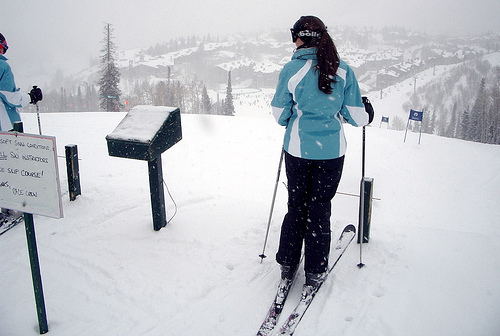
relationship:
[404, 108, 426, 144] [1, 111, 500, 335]
ski marker in snow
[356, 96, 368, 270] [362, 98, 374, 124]
ski pole in hand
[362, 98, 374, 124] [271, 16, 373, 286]
hand of girl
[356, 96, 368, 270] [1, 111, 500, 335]
ski pole in snow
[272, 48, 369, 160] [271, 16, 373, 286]
jacket on girl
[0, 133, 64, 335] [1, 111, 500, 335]
sign in snow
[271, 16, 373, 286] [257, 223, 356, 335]
girl in skis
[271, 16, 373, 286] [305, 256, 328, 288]
girl in ski boot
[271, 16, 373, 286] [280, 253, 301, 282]
girl in ski boot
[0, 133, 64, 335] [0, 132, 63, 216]
sign with warning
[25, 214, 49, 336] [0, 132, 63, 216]
pole holding warning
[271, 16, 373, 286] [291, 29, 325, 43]
girl in goggles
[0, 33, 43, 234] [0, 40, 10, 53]
person in goggles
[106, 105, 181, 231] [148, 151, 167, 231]
box on post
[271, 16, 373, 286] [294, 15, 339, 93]
girl with hair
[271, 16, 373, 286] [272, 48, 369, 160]
woman with jacket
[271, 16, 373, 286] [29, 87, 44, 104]
woman has glove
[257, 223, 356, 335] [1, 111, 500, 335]
skis in snow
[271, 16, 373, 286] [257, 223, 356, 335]
woman on skis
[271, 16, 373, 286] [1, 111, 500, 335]
woman on snow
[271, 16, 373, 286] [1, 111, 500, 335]
woman skiing on snow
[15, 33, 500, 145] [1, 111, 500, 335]
mountain covered in snow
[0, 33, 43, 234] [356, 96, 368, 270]
woman holding ski pole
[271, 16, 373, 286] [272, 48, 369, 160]
woman in jacket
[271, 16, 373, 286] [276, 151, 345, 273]
woman wearing pants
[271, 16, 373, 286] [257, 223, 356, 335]
woman in skis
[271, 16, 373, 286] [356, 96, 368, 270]
woman holding ski pole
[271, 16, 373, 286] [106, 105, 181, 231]
woman next to box